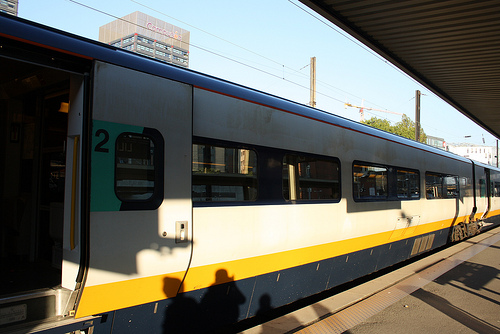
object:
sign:
[94, 130, 109, 153]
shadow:
[162, 277, 200, 334]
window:
[115, 132, 156, 200]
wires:
[119, 0, 416, 131]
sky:
[18, 0, 500, 167]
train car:
[0, 12, 477, 334]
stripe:
[74, 209, 498, 319]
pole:
[309, 57, 318, 107]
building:
[99, 11, 189, 68]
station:
[233, 0, 499, 334]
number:
[94, 128, 109, 153]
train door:
[1, 38, 93, 333]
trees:
[360, 113, 428, 144]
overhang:
[297, 0, 500, 139]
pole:
[415, 90, 422, 141]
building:
[0, 0, 18, 15]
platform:
[237, 225, 500, 334]